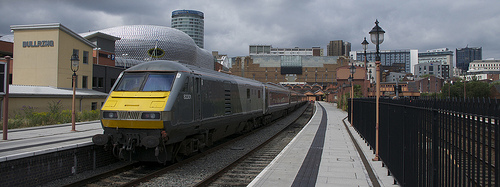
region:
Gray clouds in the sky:
[1, 0, 492, 63]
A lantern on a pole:
[370, 18, 385, 161]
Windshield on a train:
[113, 67, 175, 90]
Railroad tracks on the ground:
[217, 121, 299, 184]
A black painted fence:
[346, 95, 492, 180]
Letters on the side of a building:
[20, 39, 57, 48]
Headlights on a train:
[101, 108, 161, 120]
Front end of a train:
[95, 55, 218, 173]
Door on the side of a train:
[190, 74, 205, 123]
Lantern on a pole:
[66, 48, 81, 133]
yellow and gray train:
[101, 48, 284, 141]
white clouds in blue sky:
[427, 27, 464, 49]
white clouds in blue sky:
[439, 14, 486, 33]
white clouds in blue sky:
[390, 2, 421, 23]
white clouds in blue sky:
[261, 11, 299, 35]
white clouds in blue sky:
[77, 10, 114, 24]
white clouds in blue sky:
[127, 19, 164, 38]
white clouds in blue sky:
[231, 5, 264, 22]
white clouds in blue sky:
[247, 20, 280, 44]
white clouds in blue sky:
[215, 14, 262, 36]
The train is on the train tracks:
[18, 44, 336, 185]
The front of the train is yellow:
[106, 87, 162, 112]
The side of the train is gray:
[187, 59, 313, 129]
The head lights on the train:
[100, 105, 164, 122]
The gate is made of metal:
[358, 93, 497, 184]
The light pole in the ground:
[362, 18, 389, 165]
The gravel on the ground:
[164, 97, 316, 184]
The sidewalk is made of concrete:
[307, 125, 359, 184]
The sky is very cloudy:
[224, 5, 464, 39]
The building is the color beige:
[9, 25, 96, 97]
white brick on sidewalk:
[320, 162, 335, 178]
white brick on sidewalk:
[342, 171, 359, 185]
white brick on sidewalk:
[323, 153, 340, 172]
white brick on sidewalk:
[341, 162, 367, 182]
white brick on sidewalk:
[331, 145, 348, 167]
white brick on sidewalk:
[339, 142, 364, 173]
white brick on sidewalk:
[324, 127, 339, 152]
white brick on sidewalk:
[330, 122, 352, 152]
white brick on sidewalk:
[329, 115, 339, 137]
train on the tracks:
[91, 53, 317, 153]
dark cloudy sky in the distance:
[248, 7, 358, 37]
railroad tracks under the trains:
[283, 123, 338, 183]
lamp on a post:
[367, 12, 389, 168]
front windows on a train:
[116, 68, 179, 91]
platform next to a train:
[26, 107, 93, 170]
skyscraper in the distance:
[168, 7, 210, 41]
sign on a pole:
[63, 58, 88, 148]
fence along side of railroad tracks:
[396, 94, 493, 178]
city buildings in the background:
[253, 25, 494, 112]